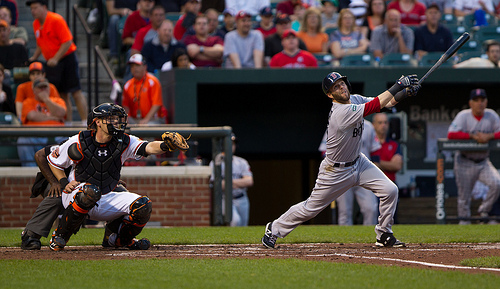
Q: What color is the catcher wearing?
A: Orange, black and white.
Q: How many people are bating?
A: One.